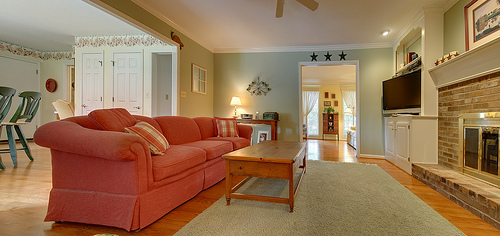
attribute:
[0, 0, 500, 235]
living room — modern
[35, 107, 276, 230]
sofa — pink, peach, large, beautiful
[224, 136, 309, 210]
table — wooden, wood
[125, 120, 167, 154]
pillow — plaid, colorful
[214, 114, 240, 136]
pillow — plaid, colorful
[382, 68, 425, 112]
television — flat, large, black, off, silver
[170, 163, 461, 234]
rug — white, grey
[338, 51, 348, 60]
star — black, large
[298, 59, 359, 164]
door — large, white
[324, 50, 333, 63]
star — black, large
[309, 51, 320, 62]
star — black, large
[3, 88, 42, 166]
chair — green, beige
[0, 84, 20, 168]
chair — green, beige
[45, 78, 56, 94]
plate — hanging, red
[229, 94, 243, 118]
lamp — on, small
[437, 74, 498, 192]
fireplace — brick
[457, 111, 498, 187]
door — glass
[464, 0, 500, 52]
picture — framed, hanging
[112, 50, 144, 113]
door — white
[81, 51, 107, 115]
door — white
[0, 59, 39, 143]
door — white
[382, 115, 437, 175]
cabinet — white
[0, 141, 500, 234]
floor — wood